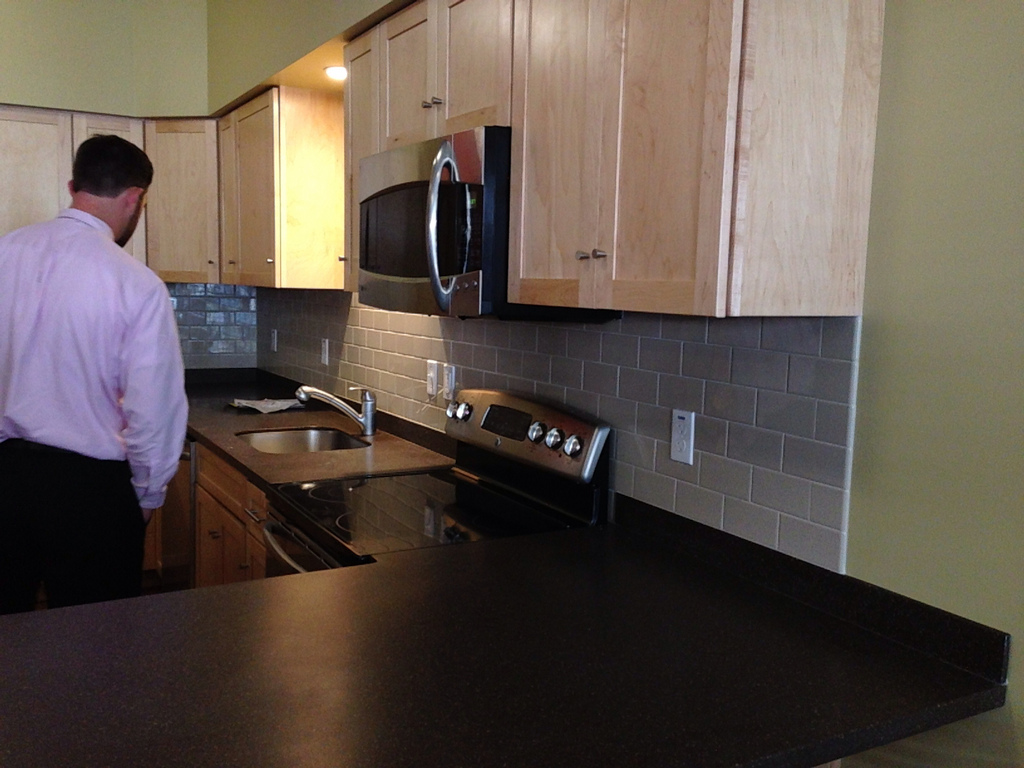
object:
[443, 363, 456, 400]
switch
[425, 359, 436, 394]
switch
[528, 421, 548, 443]
knobs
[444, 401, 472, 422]
row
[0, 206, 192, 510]
shirt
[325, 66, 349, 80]
light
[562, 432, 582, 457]
knob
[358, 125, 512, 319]
microwave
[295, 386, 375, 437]
faucet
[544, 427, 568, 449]
stove knobs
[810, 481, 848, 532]
tile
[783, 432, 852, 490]
tile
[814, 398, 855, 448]
tile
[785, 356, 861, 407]
tile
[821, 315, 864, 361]
tile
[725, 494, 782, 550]
tile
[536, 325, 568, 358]
tile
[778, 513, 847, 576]
tile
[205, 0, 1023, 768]
wall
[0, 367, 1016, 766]
counter top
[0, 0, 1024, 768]
kitchen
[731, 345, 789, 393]
tiles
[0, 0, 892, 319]
cabinets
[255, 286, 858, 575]
backsplash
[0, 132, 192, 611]
man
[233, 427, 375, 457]
sink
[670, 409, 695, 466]
outlet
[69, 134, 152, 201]
hair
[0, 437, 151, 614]
pants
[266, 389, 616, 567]
oven